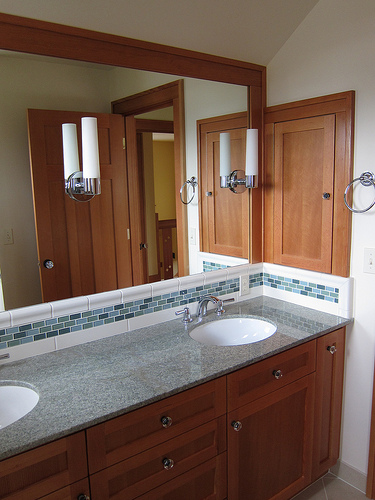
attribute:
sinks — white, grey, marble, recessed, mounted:
[1, 292, 330, 463]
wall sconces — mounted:
[51, 109, 269, 199]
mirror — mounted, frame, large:
[5, 3, 371, 284]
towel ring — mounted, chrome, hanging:
[337, 175, 374, 211]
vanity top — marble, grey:
[3, 297, 354, 454]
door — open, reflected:
[20, 105, 152, 301]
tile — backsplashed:
[8, 264, 358, 344]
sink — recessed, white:
[171, 294, 280, 352]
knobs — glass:
[51, 339, 346, 498]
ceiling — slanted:
[16, 4, 312, 68]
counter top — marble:
[8, 312, 340, 402]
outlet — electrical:
[2, 343, 16, 368]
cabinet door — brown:
[257, 114, 336, 274]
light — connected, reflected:
[226, 129, 264, 192]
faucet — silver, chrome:
[174, 289, 237, 329]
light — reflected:
[58, 113, 105, 199]